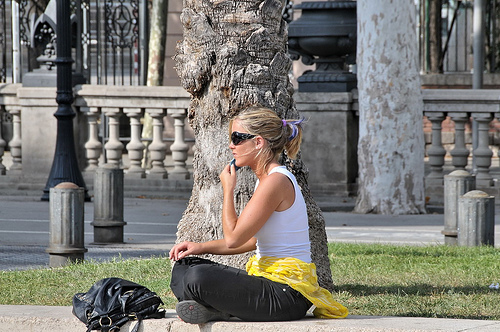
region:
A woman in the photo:
[162, 112, 339, 324]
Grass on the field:
[333, 237, 455, 310]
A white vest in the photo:
[247, 165, 310, 255]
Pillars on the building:
[50, 8, 82, 171]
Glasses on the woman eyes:
[217, 130, 259, 155]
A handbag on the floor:
[72, 262, 161, 323]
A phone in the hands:
[215, 153, 245, 185]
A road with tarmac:
[9, 202, 42, 240]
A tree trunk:
[212, 31, 299, 113]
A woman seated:
[162, 104, 345, 330]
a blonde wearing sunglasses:
[219, 106, 306, 168]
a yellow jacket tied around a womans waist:
[248, 254, 348, 320]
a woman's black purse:
[78, 272, 160, 330]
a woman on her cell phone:
[171, 104, 333, 324]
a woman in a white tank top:
[213, 108, 316, 288]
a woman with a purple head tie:
[207, 112, 309, 169]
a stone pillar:
[446, 169, 496, 254]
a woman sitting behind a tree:
[169, 3, 340, 317]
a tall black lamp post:
[39, 0, 89, 200]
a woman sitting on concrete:
[168, 111, 350, 328]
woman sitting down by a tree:
[171, 99, 351, 314]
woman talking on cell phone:
[206, 100, 319, 238]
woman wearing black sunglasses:
[224, 104, 288, 166]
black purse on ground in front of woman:
[75, 273, 170, 327]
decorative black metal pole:
[35, 4, 100, 196]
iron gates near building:
[82, 0, 158, 95]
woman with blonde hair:
[206, 99, 311, 184]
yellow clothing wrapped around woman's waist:
[240, 245, 352, 315]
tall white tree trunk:
[350, 0, 442, 222]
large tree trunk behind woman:
[173, 8, 328, 288]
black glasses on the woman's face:
[228, 130, 258, 144]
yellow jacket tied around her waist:
[243, 252, 349, 321]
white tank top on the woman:
[250, 161, 315, 266]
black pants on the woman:
[169, 253, 314, 323]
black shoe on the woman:
[175, 296, 231, 324]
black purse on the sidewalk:
[71, 278, 168, 330]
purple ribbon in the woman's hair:
[279, 114, 307, 138]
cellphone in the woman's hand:
[228, 158, 242, 173]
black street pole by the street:
[37, 0, 93, 202]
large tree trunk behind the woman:
[171, 0, 333, 287]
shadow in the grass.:
[382, 278, 430, 298]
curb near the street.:
[15, 310, 55, 322]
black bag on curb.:
[93, 279, 128, 320]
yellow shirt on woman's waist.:
[281, 265, 311, 285]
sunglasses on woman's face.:
[224, 129, 249, 146]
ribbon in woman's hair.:
[284, 113, 297, 138]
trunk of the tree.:
[219, 18, 262, 65]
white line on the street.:
[5, 225, 44, 238]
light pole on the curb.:
[48, 30, 73, 111]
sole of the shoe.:
[180, 305, 211, 325]